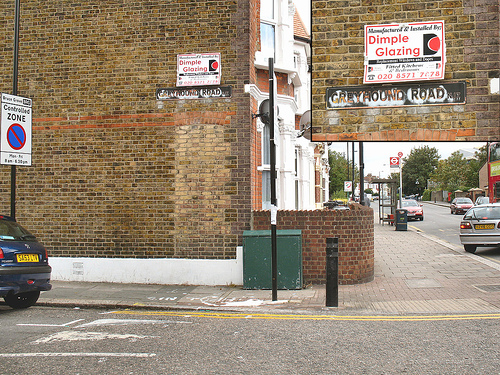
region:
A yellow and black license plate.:
[13, 251, 43, 264]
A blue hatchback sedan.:
[0, 214, 55, 306]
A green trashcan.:
[394, 208, 409, 229]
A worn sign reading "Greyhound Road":
[323, 85, 470, 107]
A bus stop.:
[373, 180, 398, 226]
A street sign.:
[2, 92, 34, 167]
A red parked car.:
[394, 198, 425, 221]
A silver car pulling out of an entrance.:
[457, 201, 497, 251]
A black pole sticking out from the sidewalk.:
[323, 237, 343, 313]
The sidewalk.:
[54, 212, 497, 316]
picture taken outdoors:
[93, 65, 429, 296]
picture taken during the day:
[68, 54, 481, 341]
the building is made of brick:
[81, 44, 208, 266]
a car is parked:
[28, 142, 71, 335]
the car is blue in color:
[6, 202, 83, 354]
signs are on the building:
[161, 37, 482, 125]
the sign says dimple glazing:
[356, 9, 496, 109]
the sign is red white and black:
[358, 6, 485, 151]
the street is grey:
[136, 322, 296, 373]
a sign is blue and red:
[4, 91, 66, 194]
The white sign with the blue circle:
[0, 89, 40, 171]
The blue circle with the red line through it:
[4, 118, 26, 152]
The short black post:
[320, 232, 343, 308]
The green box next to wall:
[238, 223, 305, 290]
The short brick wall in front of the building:
[255, 202, 379, 287]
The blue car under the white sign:
[0, 206, 57, 306]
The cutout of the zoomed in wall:
[303, 0, 498, 145]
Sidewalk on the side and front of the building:
[26, 217, 498, 313]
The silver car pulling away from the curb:
[454, 196, 499, 256]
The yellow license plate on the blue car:
[13, 251, 45, 266]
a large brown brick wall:
[1, 2, 251, 257]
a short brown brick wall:
[247, 197, 372, 284]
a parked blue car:
[0, 217, 58, 306]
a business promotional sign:
[171, 49, 221, 88]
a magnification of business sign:
[311, 0, 499, 140]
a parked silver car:
[456, 194, 498, 254]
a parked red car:
[392, 204, 426, 229]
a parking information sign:
[0, 93, 38, 173]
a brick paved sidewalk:
[362, 197, 499, 319]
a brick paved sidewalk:
[1, 269, 383, 309]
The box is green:
[226, 218, 311, 298]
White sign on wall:
[165, 48, 227, 92]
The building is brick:
[29, 16, 242, 256]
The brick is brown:
[23, 15, 256, 268]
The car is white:
[448, 200, 498, 257]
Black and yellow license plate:
[8, 239, 47, 271]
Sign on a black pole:
[0, 92, 42, 182]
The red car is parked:
[396, 194, 423, 231]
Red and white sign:
[384, 148, 406, 170]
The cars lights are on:
[451, 198, 497, 254]